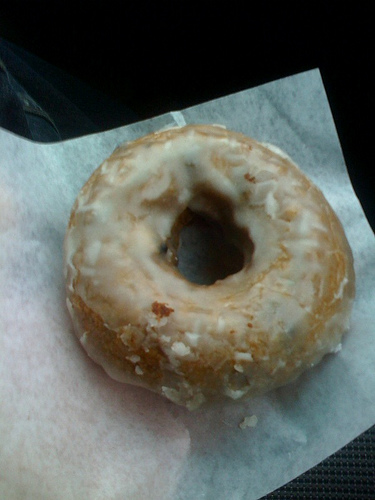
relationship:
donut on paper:
[53, 132, 366, 407] [0, 106, 370, 491]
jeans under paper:
[2, 23, 153, 122] [0, 106, 370, 491]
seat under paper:
[234, 423, 374, 500] [0, 106, 370, 491]